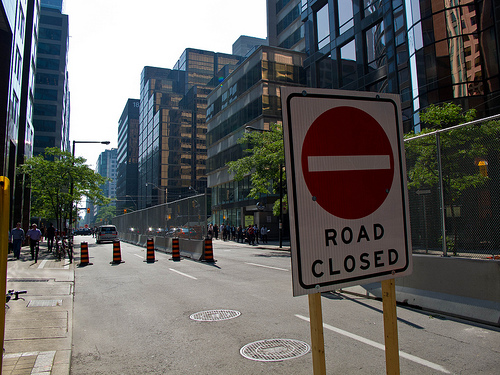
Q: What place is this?
A: It is a road.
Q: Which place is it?
A: It is a road.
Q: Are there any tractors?
A: No, there are no tractors.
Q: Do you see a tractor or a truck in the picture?
A: No, there are no tractors or trucks.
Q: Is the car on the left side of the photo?
A: Yes, the car is on the left of the image.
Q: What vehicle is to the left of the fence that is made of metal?
A: The vehicle is a car.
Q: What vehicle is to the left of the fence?
A: The vehicle is a car.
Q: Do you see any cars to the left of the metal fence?
A: Yes, there is a car to the left of the fence.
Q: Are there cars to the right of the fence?
A: No, the car is to the left of the fence.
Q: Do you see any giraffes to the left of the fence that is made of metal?
A: No, there is a car to the left of the fence.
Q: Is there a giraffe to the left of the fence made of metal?
A: No, there is a car to the left of the fence.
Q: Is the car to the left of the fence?
A: Yes, the car is to the left of the fence.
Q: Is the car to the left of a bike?
A: No, the car is to the left of the fence.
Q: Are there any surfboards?
A: No, there are no surfboards.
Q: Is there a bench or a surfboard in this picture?
A: No, there are no surfboards or benches.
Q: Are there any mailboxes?
A: No, there are no mailboxes.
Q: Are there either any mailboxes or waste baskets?
A: No, there are no mailboxes or waste baskets.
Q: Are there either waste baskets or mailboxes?
A: No, there are no mailboxes or waste baskets.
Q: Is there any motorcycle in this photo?
A: No, there are no motorcycles.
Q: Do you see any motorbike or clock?
A: No, there are no motorcycles or clocks.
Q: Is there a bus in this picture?
A: No, there are no buses.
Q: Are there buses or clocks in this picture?
A: No, there are no buses or clocks.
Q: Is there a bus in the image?
A: No, there are no buses.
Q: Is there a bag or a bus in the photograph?
A: No, there are no buses or bags.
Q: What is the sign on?
A: The sign is on the pole.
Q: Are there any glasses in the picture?
A: No, there are no glasses.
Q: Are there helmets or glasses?
A: No, there are no glasses or helmets.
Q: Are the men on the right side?
A: No, the men are on the left of the image.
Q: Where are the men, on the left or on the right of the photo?
A: The men are on the left of the image.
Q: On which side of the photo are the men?
A: The men are on the left of the image.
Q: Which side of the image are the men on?
A: The men are on the left of the image.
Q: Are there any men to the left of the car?
A: Yes, there are men to the left of the car.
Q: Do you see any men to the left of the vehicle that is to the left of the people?
A: Yes, there are men to the left of the car.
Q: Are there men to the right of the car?
A: No, the men are to the left of the car.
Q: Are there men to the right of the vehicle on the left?
A: No, the men are to the left of the car.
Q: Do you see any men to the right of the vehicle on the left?
A: No, the men are to the left of the car.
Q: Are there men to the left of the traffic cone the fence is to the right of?
A: Yes, there are men to the left of the traffic cone.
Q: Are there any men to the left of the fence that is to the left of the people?
A: Yes, there are men to the left of the fence.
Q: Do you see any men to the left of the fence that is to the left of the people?
A: Yes, there are men to the left of the fence.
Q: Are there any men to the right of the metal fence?
A: No, the men are to the left of the fence.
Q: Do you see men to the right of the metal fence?
A: No, the men are to the left of the fence.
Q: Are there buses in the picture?
A: No, there are no buses.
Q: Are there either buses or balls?
A: No, there are no buses or balls.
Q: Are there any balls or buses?
A: No, there are no buses or balls.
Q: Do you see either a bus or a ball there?
A: No, there are no buses or balls.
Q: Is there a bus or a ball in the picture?
A: No, there are no buses or balls.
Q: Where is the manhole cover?
A: The manhole cover is on the road.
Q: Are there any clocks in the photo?
A: No, there are no clocks.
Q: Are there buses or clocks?
A: No, there are no clocks or buses.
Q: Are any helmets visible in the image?
A: No, there are no helmets.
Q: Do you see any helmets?
A: No, there are no helmets.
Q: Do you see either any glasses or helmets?
A: No, there are no helmets or glasses.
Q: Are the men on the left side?
A: Yes, the men are on the left of the image.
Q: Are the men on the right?
A: No, the men are on the left of the image.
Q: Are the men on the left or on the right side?
A: The men are on the left of the image.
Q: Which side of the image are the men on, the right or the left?
A: The men are on the left of the image.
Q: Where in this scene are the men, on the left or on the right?
A: The men are on the left of the image.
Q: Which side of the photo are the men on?
A: The men are on the left of the image.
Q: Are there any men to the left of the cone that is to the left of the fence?
A: Yes, there are men to the left of the traffic cone.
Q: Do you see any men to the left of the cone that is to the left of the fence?
A: Yes, there are men to the left of the traffic cone.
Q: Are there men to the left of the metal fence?
A: Yes, there are men to the left of the fence.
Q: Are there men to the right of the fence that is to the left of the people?
A: No, the men are to the left of the fence.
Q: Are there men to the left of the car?
A: Yes, there are men to the left of the car.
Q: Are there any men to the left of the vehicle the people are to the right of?
A: Yes, there are men to the left of the car.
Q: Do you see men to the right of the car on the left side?
A: No, the men are to the left of the car.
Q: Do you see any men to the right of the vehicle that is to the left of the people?
A: No, the men are to the left of the car.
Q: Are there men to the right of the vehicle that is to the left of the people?
A: No, the men are to the left of the car.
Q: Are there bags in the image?
A: No, there are no bags.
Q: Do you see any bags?
A: No, there are no bags.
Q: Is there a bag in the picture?
A: No, there are no bags.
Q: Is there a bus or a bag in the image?
A: No, there are no bags or buses.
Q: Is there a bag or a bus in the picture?
A: No, there are no bags or buses.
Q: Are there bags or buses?
A: No, there are no bags or buses.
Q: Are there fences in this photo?
A: Yes, there is a fence.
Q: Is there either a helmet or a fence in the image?
A: Yes, there is a fence.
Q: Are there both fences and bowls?
A: No, there is a fence but no bowls.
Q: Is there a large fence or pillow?
A: Yes, there is a large fence.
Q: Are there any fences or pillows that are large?
A: Yes, the fence is large.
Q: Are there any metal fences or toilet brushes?
A: Yes, there is a metal fence.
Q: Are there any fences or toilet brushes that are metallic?
A: Yes, the fence is metallic.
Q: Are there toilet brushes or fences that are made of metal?
A: Yes, the fence is made of metal.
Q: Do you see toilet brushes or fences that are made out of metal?
A: Yes, the fence is made of metal.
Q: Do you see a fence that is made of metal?
A: Yes, there is a fence that is made of metal.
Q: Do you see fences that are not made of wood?
A: Yes, there is a fence that is made of metal.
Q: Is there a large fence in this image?
A: Yes, there is a large fence.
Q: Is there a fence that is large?
A: Yes, there is a fence that is large.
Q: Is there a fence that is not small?
A: Yes, there is a large fence.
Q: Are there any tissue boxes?
A: No, there are no tissue boxes.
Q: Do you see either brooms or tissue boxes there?
A: No, there are no tissue boxes or brooms.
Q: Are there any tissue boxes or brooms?
A: No, there are no tissue boxes or brooms.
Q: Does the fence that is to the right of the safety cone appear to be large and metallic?
A: Yes, the fence is large and metallic.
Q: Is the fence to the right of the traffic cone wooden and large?
A: No, the fence is large but metallic.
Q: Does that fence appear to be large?
A: Yes, the fence is large.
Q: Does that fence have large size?
A: Yes, the fence is large.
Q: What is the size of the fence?
A: The fence is large.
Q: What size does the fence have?
A: The fence has large size.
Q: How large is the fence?
A: The fence is large.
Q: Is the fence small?
A: No, the fence is large.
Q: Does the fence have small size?
A: No, the fence is large.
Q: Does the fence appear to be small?
A: No, the fence is large.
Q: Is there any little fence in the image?
A: No, there is a fence but it is large.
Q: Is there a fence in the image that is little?
A: No, there is a fence but it is large.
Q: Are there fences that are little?
A: No, there is a fence but it is large.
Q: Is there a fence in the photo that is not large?
A: No, there is a fence but it is large.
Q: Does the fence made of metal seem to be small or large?
A: The fence is large.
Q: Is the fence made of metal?
A: Yes, the fence is made of metal.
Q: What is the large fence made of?
A: The fence is made of metal.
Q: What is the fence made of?
A: The fence is made of metal.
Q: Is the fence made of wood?
A: No, the fence is made of metal.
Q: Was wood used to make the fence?
A: No, the fence is made of metal.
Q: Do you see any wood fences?
A: No, there is a fence but it is made of metal.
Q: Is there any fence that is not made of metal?
A: No, there is a fence but it is made of metal.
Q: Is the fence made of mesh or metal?
A: The fence is made of metal.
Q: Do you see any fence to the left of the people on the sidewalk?
A: Yes, there is a fence to the left of the people.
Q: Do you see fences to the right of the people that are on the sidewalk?
A: No, the fence is to the left of the people.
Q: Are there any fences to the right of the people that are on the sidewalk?
A: No, the fence is to the left of the people.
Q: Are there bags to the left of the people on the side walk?
A: No, there is a fence to the left of the people.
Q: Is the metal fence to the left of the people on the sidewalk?
A: Yes, the fence is to the left of the people.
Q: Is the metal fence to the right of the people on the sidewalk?
A: No, the fence is to the left of the people.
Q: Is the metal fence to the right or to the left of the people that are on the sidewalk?
A: The fence is to the left of the people.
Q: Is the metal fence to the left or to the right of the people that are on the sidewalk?
A: The fence is to the left of the people.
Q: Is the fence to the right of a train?
A: No, the fence is to the right of the cone.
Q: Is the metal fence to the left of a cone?
A: No, the fence is to the right of a cone.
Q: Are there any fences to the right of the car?
A: Yes, there is a fence to the right of the car.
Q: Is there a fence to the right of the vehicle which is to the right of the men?
A: Yes, there is a fence to the right of the car.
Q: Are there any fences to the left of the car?
A: No, the fence is to the right of the car.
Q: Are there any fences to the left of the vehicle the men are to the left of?
A: No, the fence is to the right of the car.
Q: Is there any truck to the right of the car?
A: No, there is a fence to the right of the car.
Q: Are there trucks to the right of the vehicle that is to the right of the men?
A: No, there is a fence to the right of the car.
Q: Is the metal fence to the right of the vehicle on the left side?
A: Yes, the fence is to the right of the car.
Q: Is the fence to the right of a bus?
A: No, the fence is to the right of the car.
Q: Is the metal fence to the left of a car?
A: No, the fence is to the right of a car.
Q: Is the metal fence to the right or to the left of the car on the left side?
A: The fence is to the right of the car.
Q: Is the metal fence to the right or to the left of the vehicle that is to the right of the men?
A: The fence is to the right of the car.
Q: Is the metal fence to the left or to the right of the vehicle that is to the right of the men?
A: The fence is to the right of the car.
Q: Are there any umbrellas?
A: No, there are no umbrellas.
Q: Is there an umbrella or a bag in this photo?
A: No, there are no umbrellas or bags.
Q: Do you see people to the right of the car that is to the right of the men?
A: Yes, there are people to the right of the car.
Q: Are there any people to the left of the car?
A: No, the people are to the right of the car.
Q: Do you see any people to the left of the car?
A: No, the people are to the right of the car.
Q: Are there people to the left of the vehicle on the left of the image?
A: No, the people are to the right of the car.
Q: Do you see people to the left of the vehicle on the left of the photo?
A: No, the people are to the right of the car.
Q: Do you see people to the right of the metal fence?
A: Yes, there are people to the right of the fence.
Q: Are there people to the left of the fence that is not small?
A: No, the people are to the right of the fence.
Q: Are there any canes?
A: No, there are no canes.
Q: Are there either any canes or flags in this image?
A: No, there are no canes or flags.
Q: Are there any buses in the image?
A: No, there are no buses.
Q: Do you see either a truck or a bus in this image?
A: No, there are no buses or trucks.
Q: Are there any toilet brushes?
A: No, there are no toilet brushes.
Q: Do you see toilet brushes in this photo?
A: No, there are no toilet brushes.